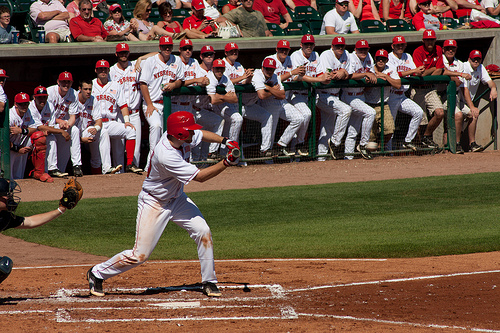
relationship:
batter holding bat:
[88, 112, 232, 308] [229, 147, 242, 158]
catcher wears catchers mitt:
[0, 174, 86, 281] [58, 175, 94, 207]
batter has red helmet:
[88, 112, 232, 308] [167, 108, 205, 136]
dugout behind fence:
[1, 32, 498, 155] [163, 76, 460, 150]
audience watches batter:
[1, 2, 499, 43] [88, 112, 232, 308]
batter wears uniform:
[88, 112, 232, 308] [90, 129, 219, 293]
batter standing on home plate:
[88, 112, 232, 308] [50, 281, 297, 326]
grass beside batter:
[215, 182, 499, 256] [88, 112, 232, 308]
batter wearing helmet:
[88, 112, 232, 308] [167, 108, 205, 136]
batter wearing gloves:
[88, 112, 232, 308] [220, 136, 242, 167]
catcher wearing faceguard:
[0, 174, 86, 281] [6, 179, 20, 214]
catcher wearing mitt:
[0, 174, 86, 281] [58, 175, 94, 207]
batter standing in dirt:
[88, 112, 232, 308] [32, 279, 424, 320]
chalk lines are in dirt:
[30, 272, 499, 325] [19, 258, 500, 332]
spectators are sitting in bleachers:
[1, 2, 499, 43] [270, 1, 328, 33]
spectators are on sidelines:
[1, 2, 499, 43] [3, 3, 500, 154]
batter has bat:
[88, 112, 232, 308] [229, 147, 242, 158]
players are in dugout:
[13, 32, 489, 128] [1, 32, 498, 155]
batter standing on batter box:
[88, 112, 232, 308] [54, 284, 290, 303]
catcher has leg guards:
[0, 174, 86, 281] [1, 249, 14, 284]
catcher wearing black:
[0, 174, 86, 281] [0, 210, 22, 235]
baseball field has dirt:
[4, 171, 499, 328] [32, 279, 424, 320]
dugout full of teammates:
[1, 32, 498, 155] [13, 32, 489, 128]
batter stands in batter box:
[88, 112, 232, 308] [54, 284, 290, 303]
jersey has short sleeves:
[138, 133, 205, 199] [178, 132, 201, 191]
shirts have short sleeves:
[12, 61, 490, 99] [140, 62, 189, 82]